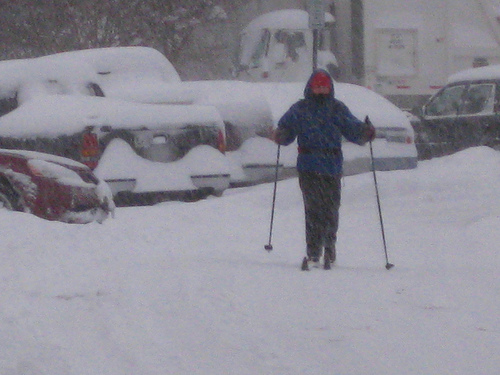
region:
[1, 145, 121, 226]
hood of small red sedan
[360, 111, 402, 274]
ski pole in left hand of cross country skiier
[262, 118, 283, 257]
ski pole in right hand of cross country skiier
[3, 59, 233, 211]
rear of black truck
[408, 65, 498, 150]
small black sedan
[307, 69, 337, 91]
red ski cap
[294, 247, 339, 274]
cross country skis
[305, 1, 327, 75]
white and green street sign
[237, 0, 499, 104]
white delivery truck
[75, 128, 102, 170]
red driver's side tail light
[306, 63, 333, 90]
Person red hat on head.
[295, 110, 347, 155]
Person wearing blue jacket.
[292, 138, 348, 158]
Black strip on blue jacket.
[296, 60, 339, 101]
Person has hood up on head.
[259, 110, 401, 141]
Person wearing gloves on hands.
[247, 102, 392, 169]
Person holding ski poles.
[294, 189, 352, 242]
Person wearing black pants.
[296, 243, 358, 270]
Person has skis on feet.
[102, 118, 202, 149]
Black truck covered in snow.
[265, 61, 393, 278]
Person wearing heavy jacket in the snow.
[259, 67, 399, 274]
Individual wearing a blue winter jacket.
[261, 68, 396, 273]
Individual using ski poles in the snow.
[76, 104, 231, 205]
Bed of truck with snow covering it.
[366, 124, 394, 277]
Black ski pole.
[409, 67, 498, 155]
Vehicle covered in snow.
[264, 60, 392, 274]
Person using ski poles to walk in the snow.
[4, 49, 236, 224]
Vehicles partially buried under snow.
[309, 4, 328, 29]
Street sign covered in snow.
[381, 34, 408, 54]
Black printing on the side of a large truck.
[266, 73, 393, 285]
a person standing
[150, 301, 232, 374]
the snow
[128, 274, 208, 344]
the snow is white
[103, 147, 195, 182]
snow on the truck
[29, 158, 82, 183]
a headlight on the car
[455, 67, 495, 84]
snow on top of the car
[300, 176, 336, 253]
person wearing black pants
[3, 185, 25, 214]
a tire on the car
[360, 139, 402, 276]
a pole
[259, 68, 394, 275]
Person on ski's walking on the snow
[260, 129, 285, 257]
left ski pole's held by the person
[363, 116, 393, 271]
right ski pole held by the person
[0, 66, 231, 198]
Car covered by snow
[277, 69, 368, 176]
Blue hooded jacket worn by the person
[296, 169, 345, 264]
black pants worn by the person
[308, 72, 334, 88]
Red bonnet on the head of the person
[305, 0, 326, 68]
Street sign next to the car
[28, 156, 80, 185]
right head light of the red car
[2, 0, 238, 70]
Brown tree on the back ground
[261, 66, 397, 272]
Person on skis and holding ski poles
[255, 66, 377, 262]
Skier wearing blue jacket and red hat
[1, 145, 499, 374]
Deep snow covering street and sidewalk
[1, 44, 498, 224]
Line of snow covered vehicles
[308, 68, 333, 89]
red hat on a person